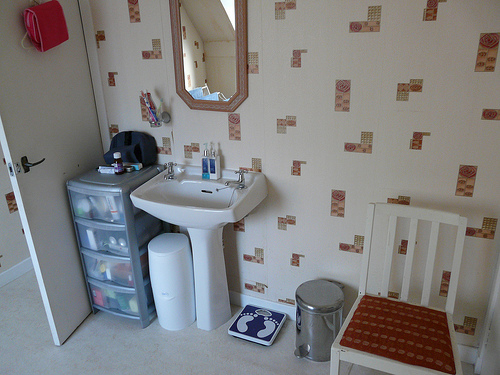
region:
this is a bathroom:
[155, 136, 438, 371]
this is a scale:
[211, 288, 306, 365]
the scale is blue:
[228, 281, 248, 366]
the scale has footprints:
[217, 279, 303, 374]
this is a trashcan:
[283, 240, 337, 325]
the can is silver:
[285, 273, 304, 313]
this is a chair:
[363, 206, 441, 371]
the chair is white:
[389, 219, 433, 335]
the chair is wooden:
[413, 136, 428, 321]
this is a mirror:
[151, 57, 181, 74]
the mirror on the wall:
[169, 0, 247, 111]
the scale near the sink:
[227, 304, 285, 345]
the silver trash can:
[293, 280, 343, 362]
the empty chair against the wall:
[329, 202, 466, 374]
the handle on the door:
[20, 156, 45, 171]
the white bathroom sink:
[130, 161, 269, 332]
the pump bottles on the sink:
[201, 141, 220, 179]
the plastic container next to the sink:
[65, 162, 170, 327]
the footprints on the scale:
[237, 312, 277, 338]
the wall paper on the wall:
[89, 1, 499, 347]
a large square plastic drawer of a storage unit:
[67, 183, 122, 221]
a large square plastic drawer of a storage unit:
[72, 218, 131, 256]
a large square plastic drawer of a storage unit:
[81, 249, 136, 286]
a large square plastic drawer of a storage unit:
[85, 281, 142, 318]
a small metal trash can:
[291, 277, 341, 359]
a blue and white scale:
[230, 295, 281, 343]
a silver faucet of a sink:
[164, 159, 177, 179]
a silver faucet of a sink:
[226, 167, 247, 191]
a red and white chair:
[332, 195, 463, 373]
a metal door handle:
[20, 153, 45, 174]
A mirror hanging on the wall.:
[168, 1, 249, 109]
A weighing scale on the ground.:
[227, 300, 289, 347]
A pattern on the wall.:
[452, 160, 479, 197]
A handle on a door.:
[17, 152, 46, 173]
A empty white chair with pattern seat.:
[327, 199, 468, 374]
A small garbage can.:
[288, 276, 347, 367]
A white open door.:
[1, 0, 107, 347]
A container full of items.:
[63, 152, 168, 328]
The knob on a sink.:
[223, 168, 250, 190]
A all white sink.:
[129, 159, 270, 331]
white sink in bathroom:
[155, 137, 254, 329]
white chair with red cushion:
[365, 195, 480, 372]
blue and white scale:
[235, 304, 283, 349]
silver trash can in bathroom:
[298, 287, 334, 357]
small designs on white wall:
[314, 77, 391, 174]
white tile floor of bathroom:
[88, 314, 164, 369]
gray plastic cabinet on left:
[63, 190, 176, 366]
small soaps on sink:
[199, 147, 229, 180]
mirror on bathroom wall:
[171, 12, 260, 125]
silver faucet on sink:
[237, 166, 251, 194]